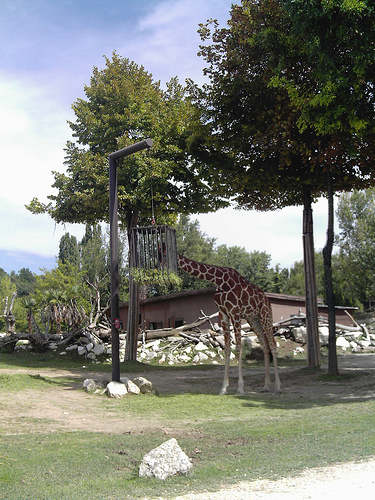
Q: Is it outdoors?
A: Yes, it is outdoors.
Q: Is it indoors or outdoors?
A: It is outdoors.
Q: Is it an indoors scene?
A: No, it is outdoors.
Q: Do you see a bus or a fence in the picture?
A: No, there are no fences or buses.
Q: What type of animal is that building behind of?
A: The building is behind the giraffe.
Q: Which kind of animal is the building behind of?
A: The building is behind the giraffe.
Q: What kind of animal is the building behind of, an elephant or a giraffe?
A: The building is behind a giraffe.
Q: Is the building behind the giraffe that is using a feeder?
A: Yes, the building is behind the giraffe.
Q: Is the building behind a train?
A: No, the building is behind the giraffe.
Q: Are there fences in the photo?
A: No, there are no fences.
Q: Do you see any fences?
A: No, there are no fences.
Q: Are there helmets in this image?
A: No, there are no helmets.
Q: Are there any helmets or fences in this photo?
A: No, there are no helmets or fences.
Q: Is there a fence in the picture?
A: No, there are no fences.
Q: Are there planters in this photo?
A: No, there are no planters.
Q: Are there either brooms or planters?
A: No, there are no planters or brooms.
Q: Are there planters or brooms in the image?
A: No, there are no planters or brooms.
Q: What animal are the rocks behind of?
A: The rocks are behind the giraffe.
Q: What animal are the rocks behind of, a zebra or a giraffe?
A: The rocks are behind a giraffe.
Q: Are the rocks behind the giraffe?
A: Yes, the rocks are behind the giraffe.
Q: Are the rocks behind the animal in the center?
A: Yes, the rocks are behind the giraffe.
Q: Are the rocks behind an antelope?
A: No, the rocks are behind the giraffe.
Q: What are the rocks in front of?
A: The rocks are in front of the building.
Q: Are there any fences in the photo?
A: No, there are no fences.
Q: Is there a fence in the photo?
A: No, there are no fences.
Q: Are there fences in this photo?
A: No, there are no fences.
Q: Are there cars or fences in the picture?
A: No, there are no fences or cars.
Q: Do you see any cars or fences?
A: No, there are no fences or cars.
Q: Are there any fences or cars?
A: No, there are no fences or cars.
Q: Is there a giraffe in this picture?
A: Yes, there is a giraffe.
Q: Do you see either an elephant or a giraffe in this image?
A: Yes, there is a giraffe.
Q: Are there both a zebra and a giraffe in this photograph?
A: No, there is a giraffe but no zebras.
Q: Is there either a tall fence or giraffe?
A: Yes, there is a tall giraffe.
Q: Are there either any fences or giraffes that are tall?
A: Yes, the giraffe is tall.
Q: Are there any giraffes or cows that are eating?
A: Yes, the giraffe is eating.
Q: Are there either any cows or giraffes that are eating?
A: Yes, the giraffe is eating.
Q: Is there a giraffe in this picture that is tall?
A: Yes, there is a tall giraffe.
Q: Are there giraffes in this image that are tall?
A: Yes, there is a giraffe that is tall.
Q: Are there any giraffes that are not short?
A: Yes, there is a tall giraffe.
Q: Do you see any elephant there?
A: No, there are no elephants.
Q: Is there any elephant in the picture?
A: No, there are no elephants.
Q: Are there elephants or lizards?
A: No, there are no elephants or lizards.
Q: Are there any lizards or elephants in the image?
A: No, there are no elephants or lizards.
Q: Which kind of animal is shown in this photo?
A: The animal is a giraffe.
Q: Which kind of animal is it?
A: The animal is a giraffe.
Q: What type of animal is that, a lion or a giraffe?
A: This is a giraffe.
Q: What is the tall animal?
A: The animal is a giraffe.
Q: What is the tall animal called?
A: The animal is a giraffe.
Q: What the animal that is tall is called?
A: The animal is a giraffe.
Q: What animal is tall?
A: The animal is a giraffe.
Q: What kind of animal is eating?
A: The animal is a giraffe.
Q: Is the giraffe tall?
A: Yes, the giraffe is tall.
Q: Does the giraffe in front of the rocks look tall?
A: Yes, the giraffe is tall.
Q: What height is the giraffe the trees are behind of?
A: The giraffe is tall.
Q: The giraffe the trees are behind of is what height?
A: The giraffe is tall.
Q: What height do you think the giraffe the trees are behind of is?
A: The giraffe is tall.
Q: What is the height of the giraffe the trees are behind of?
A: The giraffe is tall.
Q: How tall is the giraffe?
A: The giraffe is tall.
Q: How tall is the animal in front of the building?
A: The giraffe is tall.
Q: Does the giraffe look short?
A: No, the giraffe is tall.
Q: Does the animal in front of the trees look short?
A: No, the giraffe is tall.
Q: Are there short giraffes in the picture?
A: No, there is a giraffe but it is tall.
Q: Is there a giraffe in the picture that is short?
A: No, there is a giraffe but it is tall.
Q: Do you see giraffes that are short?
A: No, there is a giraffe but it is tall.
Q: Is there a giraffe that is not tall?
A: No, there is a giraffe but it is tall.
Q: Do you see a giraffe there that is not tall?
A: No, there is a giraffe but it is tall.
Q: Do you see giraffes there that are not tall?
A: No, there is a giraffe but it is tall.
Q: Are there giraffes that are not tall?
A: No, there is a giraffe but it is tall.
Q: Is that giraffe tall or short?
A: The giraffe is tall.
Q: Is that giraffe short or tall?
A: The giraffe is tall.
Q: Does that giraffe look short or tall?
A: The giraffe is tall.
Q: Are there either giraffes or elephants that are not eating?
A: No, there is a giraffe but it is eating.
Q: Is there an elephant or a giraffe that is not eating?
A: No, there is a giraffe but it is eating.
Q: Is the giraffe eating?
A: Yes, the giraffe is eating.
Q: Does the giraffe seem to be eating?
A: Yes, the giraffe is eating.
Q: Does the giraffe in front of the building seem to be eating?
A: Yes, the giraffe is eating.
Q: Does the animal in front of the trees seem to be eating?
A: Yes, the giraffe is eating.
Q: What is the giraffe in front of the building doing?
A: The giraffe is eating.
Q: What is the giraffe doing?
A: The giraffe is eating.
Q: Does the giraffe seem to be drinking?
A: No, the giraffe is eating.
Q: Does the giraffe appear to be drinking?
A: No, the giraffe is eating.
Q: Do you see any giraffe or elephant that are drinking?
A: No, there is a giraffe but it is eating.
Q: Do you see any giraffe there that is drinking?
A: No, there is a giraffe but it is eating.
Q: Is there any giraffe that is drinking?
A: No, there is a giraffe but it is eating.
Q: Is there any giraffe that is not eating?
A: No, there is a giraffe but it is eating.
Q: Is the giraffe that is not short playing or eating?
A: The giraffe is eating.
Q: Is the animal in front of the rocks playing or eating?
A: The giraffe is eating.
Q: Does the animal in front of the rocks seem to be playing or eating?
A: The giraffe is eating.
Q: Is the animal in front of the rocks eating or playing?
A: The giraffe is eating.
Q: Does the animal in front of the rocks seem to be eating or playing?
A: The giraffe is eating.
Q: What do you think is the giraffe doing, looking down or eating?
A: The giraffe is eating.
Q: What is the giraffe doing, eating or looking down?
A: The giraffe is eating.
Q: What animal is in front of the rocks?
A: The giraffe is in front of the rocks.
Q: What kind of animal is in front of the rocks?
A: The animal is a giraffe.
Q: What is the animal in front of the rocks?
A: The animal is a giraffe.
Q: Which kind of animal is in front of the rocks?
A: The animal is a giraffe.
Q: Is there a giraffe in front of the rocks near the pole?
A: Yes, there is a giraffe in front of the rocks.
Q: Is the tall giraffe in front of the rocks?
A: Yes, the giraffe is in front of the rocks.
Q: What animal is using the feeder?
A: The animal is a giraffe.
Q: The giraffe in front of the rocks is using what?
A: The giraffe is using a feeder.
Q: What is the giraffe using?
A: The giraffe is using a feeder.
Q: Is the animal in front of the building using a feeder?
A: Yes, the giraffe is using a feeder.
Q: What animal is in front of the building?
A: The animal is a giraffe.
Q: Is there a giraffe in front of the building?
A: Yes, there is a giraffe in front of the building.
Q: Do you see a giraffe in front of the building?
A: Yes, there is a giraffe in front of the building.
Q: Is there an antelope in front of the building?
A: No, there is a giraffe in front of the building.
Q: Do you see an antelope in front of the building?
A: No, there is a giraffe in front of the building.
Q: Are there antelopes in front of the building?
A: No, there is a giraffe in front of the building.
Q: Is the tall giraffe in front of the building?
A: Yes, the giraffe is in front of the building.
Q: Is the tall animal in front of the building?
A: Yes, the giraffe is in front of the building.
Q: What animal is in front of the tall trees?
A: The giraffe is in front of the trees.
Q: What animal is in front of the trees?
A: The giraffe is in front of the trees.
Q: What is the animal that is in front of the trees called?
A: The animal is a giraffe.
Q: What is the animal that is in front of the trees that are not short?
A: The animal is a giraffe.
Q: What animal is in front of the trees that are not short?
A: The animal is a giraffe.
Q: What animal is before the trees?
A: The animal is a giraffe.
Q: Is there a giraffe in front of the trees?
A: Yes, there is a giraffe in front of the trees.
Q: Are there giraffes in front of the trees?
A: Yes, there is a giraffe in front of the trees.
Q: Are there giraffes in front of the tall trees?
A: Yes, there is a giraffe in front of the trees.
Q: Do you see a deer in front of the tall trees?
A: No, there is a giraffe in front of the trees.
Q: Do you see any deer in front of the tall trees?
A: No, there is a giraffe in front of the trees.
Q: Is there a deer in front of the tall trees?
A: No, there is a giraffe in front of the trees.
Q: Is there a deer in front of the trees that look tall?
A: No, there is a giraffe in front of the trees.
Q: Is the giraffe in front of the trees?
A: Yes, the giraffe is in front of the trees.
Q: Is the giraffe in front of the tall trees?
A: Yes, the giraffe is in front of the trees.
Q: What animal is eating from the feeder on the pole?
A: The giraffe is eating from the feeder.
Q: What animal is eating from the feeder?
A: The giraffe is eating from the feeder.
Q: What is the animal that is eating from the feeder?
A: The animal is a giraffe.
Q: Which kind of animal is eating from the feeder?
A: The animal is a giraffe.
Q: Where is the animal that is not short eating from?
A: The giraffe is eating from the feeder.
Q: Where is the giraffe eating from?
A: The giraffe is eating from the feeder.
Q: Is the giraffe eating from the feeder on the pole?
A: Yes, the giraffe is eating from the feeder.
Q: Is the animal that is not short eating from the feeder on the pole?
A: Yes, the giraffe is eating from the feeder.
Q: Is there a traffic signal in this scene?
A: No, there are no traffic lights.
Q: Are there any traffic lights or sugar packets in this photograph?
A: No, there are no traffic lights or sugar packets.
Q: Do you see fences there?
A: No, there are no fences.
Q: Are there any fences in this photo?
A: No, there are no fences.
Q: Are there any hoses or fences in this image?
A: No, there are no fences or hoses.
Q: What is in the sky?
A: The clouds are in the sky.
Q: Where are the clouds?
A: The clouds are in the sky.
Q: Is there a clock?
A: No, there are no clocks.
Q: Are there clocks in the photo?
A: No, there are no clocks.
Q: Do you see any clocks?
A: No, there are no clocks.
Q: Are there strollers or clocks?
A: No, there are no clocks or strollers.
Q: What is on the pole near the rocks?
A: The feeder is on the pole.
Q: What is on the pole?
A: The feeder is on the pole.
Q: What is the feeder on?
A: The feeder is on the pole.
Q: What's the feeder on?
A: The feeder is on the pole.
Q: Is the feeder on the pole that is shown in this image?
A: Yes, the feeder is on the pole.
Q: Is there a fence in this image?
A: No, there are no fences.